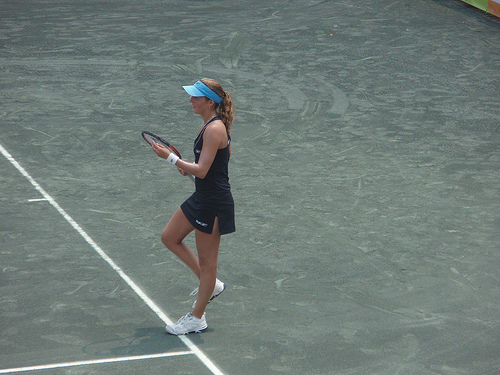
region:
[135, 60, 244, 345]
Woman playing tennis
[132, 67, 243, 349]
Woman with ponytail playing tennis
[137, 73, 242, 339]
Woman in blue visor playing tennis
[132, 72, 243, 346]
Woman with a tennis racket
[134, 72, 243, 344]
Woman getting ready to play tennis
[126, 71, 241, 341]
Woman on tennis court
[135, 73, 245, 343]
Woman in tennis outfit with racket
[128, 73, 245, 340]
Woman in black tennis outfit with racket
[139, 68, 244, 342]
Woman on a tennis court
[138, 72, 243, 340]
Woman with ponytail on tennis court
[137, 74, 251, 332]
woman playing tennis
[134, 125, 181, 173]
red and black tennis racket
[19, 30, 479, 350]
dark grey tennis court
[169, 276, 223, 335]
bright white tennis shoes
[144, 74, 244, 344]
woman wearing a short dress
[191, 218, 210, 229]
small white logo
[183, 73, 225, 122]
woman wearing a blue visor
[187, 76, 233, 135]
woman with her hair up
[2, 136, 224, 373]
white painted lines on the court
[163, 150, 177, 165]
thick white wrist band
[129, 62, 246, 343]
The girl plays tennis.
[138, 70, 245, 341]
The girl wears a visor.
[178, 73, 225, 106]
The visor is blue.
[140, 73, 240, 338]
The girl holds a racket.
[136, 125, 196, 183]
The racket is red and black.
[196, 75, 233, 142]
The hair is blonde.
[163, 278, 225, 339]
The shoes are white.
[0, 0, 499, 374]
The tennis court is green.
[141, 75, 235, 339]
The girl wears black.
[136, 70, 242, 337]
The girl is athletic.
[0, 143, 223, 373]
white lines on the tennis court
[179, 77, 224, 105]
a blue visor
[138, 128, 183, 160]
a red and black tennis racket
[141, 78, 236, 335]
a woman wearing white sneakers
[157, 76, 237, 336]
a woman wearing a black outfit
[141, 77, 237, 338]
the woman is wearing a white wrist band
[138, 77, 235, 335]
a woman with red hair wearing a blue visor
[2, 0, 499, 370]
a green colored tennis court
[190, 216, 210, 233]
white blurred writing on a black background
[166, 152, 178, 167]
black writing on a white wristband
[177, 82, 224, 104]
Blue visor on woman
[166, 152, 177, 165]
Sweatband on woman's wrist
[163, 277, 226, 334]
White tennis shoes on woman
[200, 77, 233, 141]
Tennis players hair in ponytail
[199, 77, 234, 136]
Blonde hair on woman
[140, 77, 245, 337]
Woman standing on tennis court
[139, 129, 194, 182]
Tennis racket in woman's hands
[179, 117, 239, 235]
Black tennis skirt on woman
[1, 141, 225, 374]
White play area boundary lines on court